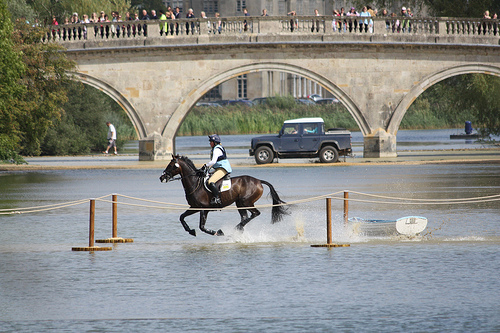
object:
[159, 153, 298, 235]
horse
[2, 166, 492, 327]
water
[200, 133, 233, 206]
man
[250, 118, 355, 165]
truck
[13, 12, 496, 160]
bridge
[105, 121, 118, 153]
man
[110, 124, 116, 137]
shirt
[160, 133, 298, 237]
horse and rider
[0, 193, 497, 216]
rope course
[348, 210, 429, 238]
boat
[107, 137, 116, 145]
shorts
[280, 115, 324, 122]
top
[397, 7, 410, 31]
person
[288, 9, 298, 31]
person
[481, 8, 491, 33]
person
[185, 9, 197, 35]
people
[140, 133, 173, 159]
stone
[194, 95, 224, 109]
cars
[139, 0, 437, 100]
building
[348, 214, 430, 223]
blue trim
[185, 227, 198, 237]
front feet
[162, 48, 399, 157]
arches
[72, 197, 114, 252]
poles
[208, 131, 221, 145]
helmet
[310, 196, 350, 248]
pole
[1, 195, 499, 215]
rope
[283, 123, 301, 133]
window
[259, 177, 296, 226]
tail